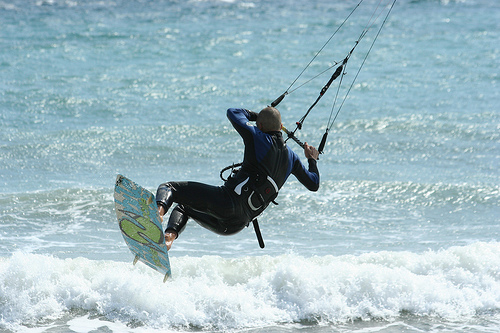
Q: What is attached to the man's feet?
A: Surfboard.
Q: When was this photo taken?
A: Daytime.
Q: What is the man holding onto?
A: Parasail.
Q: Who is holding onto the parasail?
A: Man.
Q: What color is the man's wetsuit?
A: Black.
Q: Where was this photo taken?
A: Ocean.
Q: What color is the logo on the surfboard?
A: Green.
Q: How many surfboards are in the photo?
A: One.